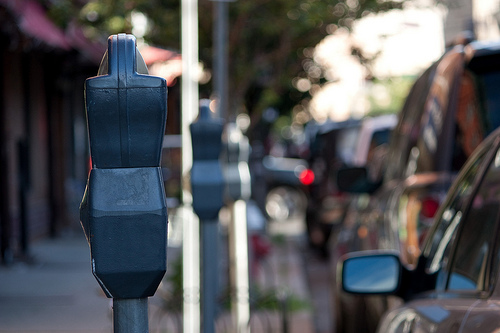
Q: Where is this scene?
A: Street.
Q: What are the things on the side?
A: Parking meters.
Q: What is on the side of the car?
A: Mirrors.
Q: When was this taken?
A: Morning.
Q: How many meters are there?
A: Two.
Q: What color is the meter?
A: Black.